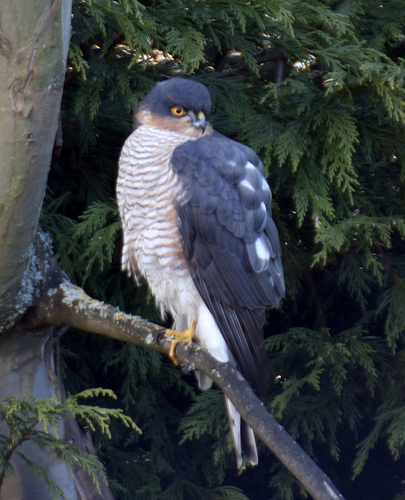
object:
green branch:
[0, 385, 122, 498]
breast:
[117, 150, 201, 246]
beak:
[192, 111, 207, 130]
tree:
[224, 14, 398, 153]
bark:
[3, 1, 77, 311]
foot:
[159, 320, 198, 363]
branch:
[33, 224, 349, 498]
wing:
[172, 126, 288, 313]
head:
[135, 74, 215, 141]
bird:
[111, 71, 309, 394]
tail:
[225, 400, 260, 475]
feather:
[227, 410, 263, 467]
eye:
[168, 103, 185, 120]